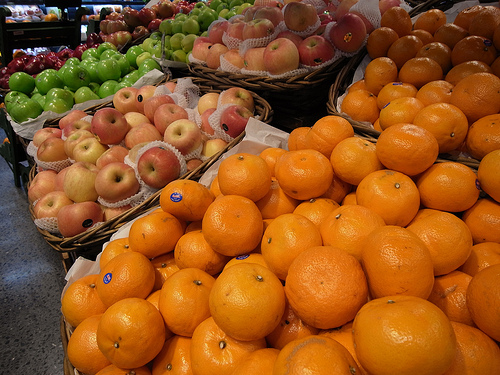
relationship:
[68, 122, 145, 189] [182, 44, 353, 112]
apples in basket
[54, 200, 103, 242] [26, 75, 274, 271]
apple sitting in basket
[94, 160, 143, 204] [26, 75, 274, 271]
apple sitting in basket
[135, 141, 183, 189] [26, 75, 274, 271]
apple sitting in basket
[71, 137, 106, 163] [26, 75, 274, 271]
apple sitting in basket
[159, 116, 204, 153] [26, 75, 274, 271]
apple sitting in basket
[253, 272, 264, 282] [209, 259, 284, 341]
stem holding orange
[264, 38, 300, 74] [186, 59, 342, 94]
apples in basket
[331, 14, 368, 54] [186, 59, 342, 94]
apples in basket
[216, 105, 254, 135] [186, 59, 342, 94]
apples in basket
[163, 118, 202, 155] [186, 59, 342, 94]
apple in basket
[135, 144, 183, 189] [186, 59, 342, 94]
apple in basket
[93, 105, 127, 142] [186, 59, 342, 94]
apples in basket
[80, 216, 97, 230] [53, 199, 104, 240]
sticker on apple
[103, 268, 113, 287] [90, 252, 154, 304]
sticker on orange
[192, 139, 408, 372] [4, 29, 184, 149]
apples in bin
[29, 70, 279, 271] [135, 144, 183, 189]
basket with apple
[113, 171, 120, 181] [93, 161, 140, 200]
stem of apple